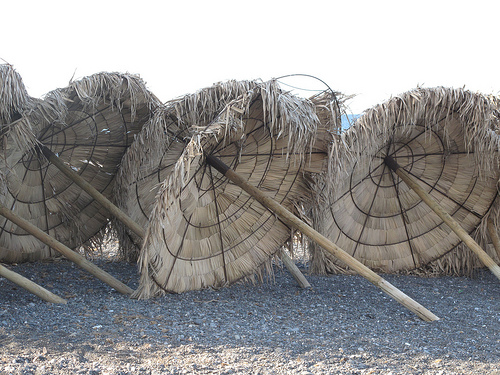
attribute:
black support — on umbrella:
[379, 159, 428, 277]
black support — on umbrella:
[396, 138, 464, 207]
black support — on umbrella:
[393, 141, 483, 164]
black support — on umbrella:
[393, 100, 443, 155]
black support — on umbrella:
[326, 149, 395, 204]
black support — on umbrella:
[341, 159, 389, 265]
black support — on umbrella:
[194, 150, 240, 285]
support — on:
[205, 180, 219, 195]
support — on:
[211, 199, 222, 236]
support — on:
[208, 208, 234, 235]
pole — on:
[260, 192, 327, 255]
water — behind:
[337, 112, 358, 130]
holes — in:
[60, 148, 112, 182]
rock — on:
[345, 344, 368, 362]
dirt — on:
[83, 306, 124, 335]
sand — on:
[322, 334, 371, 356]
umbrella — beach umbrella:
[133, 71, 439, 325]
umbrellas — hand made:
[1, 60, 499, 325]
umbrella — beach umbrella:
[306, 87, 496, 287]